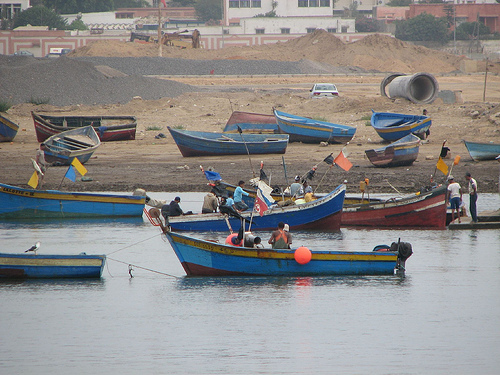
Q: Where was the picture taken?
A: On the water's edge.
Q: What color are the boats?
A: Blue and red.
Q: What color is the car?
A: White.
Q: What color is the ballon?
A: Orange.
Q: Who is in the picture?
A: Fisherman.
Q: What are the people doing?
A: Fishing.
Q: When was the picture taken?
A: Daytime.